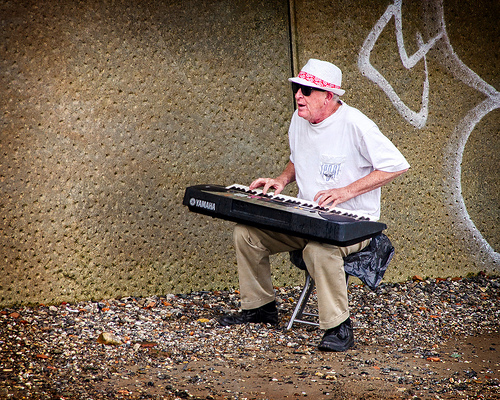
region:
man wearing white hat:
[318, 68, 333, 76]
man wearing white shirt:
[304, 132, 314, 154]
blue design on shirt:
[320, 157, 342, 182]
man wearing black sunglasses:
[287, 85, 315, 96]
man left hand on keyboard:
[249, 177, 285, 196]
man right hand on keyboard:
[316, 179, 338, 212]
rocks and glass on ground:
[168, 312, 205, 343]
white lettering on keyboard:
[193, 196, 220, 213]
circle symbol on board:
[185, 196, 197, 207]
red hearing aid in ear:
[326, 92, 333, 104]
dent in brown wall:
[113, 286, 120, 294]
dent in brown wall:
[130, 279, 140, 289]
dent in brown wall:
[143, 277, 157, 288]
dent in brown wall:
[4, 285, 14, 294]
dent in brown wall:
[13, 288, 22, 297]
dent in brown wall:
[22, 288, 31, 301]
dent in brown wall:
[102, 150, 112, 159]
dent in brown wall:
[126, 154, 138, 165]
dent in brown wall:
[176, 118, 186, 131]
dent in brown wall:
[397, 178, 404, 189]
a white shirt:
[323, 128, 360, 153]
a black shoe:
[318, 334, 343, 350]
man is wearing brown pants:
[312, 249, 352, 319]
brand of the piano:
[188, 198, 215, 209]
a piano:
[188, 182, 355, 234]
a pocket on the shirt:
[320, 149, 344, 178]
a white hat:
[285, 60, 347, 90]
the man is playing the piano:
[242, 174, 341, 216]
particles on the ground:
[117, 309, 184, 345]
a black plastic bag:
[363, 252, 383, 277]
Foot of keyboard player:
[219, 303, 283, 329]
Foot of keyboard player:
[308, 315, 363, 357]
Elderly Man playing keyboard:
[183, 51, 414, 353]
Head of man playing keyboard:
[286, 55, 356, 122]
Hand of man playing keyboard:
[311, 183, 356, 211]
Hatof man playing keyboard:
[284, 54, 354, 98]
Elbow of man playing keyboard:
[374, 155, 414, 182]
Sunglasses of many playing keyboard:
[282, 78, 322, 93]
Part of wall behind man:
[24, 54, 126, 126]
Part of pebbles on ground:
[45, 318, 149, 356]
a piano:
[171, 171, 387, 256]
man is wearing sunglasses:
[286, 80, 313, 96]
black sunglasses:
[289, 80, 312, 97]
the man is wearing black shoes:
[321, 331, 343, 351]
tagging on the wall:
[363, 20, 470, 111]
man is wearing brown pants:
[308, 261, 346, 326]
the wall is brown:
[39, 67, 148, 167]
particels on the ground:
[61, 301, 128, 344]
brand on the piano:
[189, 198, 218, 217]